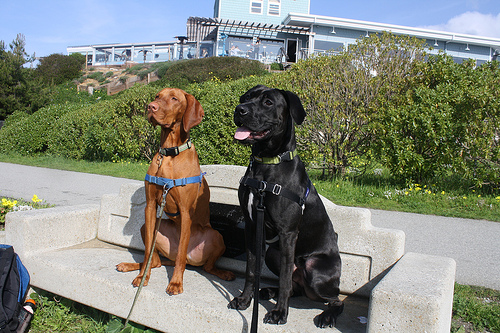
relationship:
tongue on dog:
[231, 120, 246, 144] [224, 78, 342, 327]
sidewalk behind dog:
[1, 161, 106, 213] [113, 53, 234, 311]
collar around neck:
[142, 138, 206, 174] [159, 127, 219, 169]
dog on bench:
[224, 78, 342, 327] [36, 146, 431, 332]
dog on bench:
[113, 53, 234, 311] [36, 146, 431, 332]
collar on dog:
[142, 138, 206, 174] [113, 53, 234, 311]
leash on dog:
[103, 219, 183, 333] [113, 53, 234, 311]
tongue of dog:
[231, 120, 246, 144] [224, 78, 342, 327]